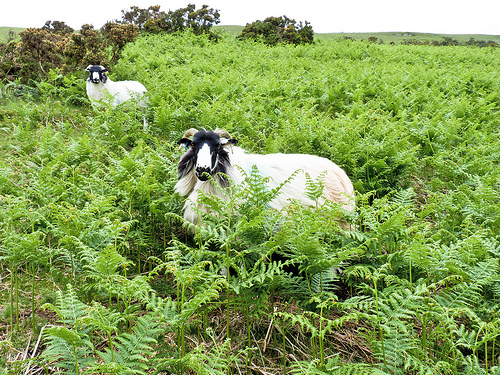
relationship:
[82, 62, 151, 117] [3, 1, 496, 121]
goat in distance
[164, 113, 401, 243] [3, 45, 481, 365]
goat in field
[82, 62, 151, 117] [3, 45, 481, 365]
goat in field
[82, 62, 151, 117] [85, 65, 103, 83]
goat with black face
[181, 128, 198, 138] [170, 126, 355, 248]
horn on goat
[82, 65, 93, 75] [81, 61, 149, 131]
horn on goat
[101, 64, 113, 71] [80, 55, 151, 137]
horn on goat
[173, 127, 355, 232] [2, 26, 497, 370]
sheep among grass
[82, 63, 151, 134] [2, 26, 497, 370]
sheep among grass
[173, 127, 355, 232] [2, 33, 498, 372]
sheep in field of ferns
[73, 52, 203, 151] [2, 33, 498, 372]
sheep in field of ferns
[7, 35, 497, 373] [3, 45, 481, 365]
fern in a field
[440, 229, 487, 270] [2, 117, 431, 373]
fern in a field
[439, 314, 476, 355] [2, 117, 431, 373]
fern in a field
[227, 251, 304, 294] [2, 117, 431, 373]
fern in a field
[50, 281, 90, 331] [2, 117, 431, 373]
fern in a field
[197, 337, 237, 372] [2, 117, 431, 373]
fern in a field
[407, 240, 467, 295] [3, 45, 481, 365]
fern in a field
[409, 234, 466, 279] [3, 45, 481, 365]
fern in a field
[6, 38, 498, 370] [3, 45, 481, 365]
green fern in a field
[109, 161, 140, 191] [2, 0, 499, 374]
fern in a field